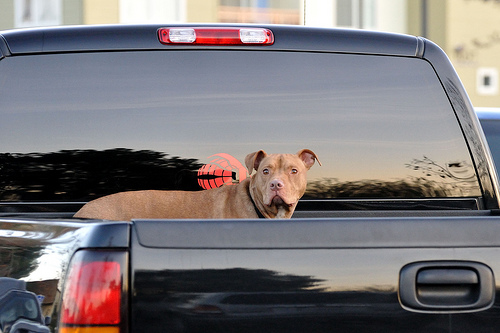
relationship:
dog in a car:
[72, 150, 321, 220] [1, 25, 500, 332]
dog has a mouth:
[72, 150, 321, 220] [266, 194, 296, 208]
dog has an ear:
[72, 150, 321, 220] [245, 150, 264, 174]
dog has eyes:
[72, 150, 321, 220] [262, 166, 300, 177]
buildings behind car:
[1, 1, 499, 113] [1, 25, 500, 332]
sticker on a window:
[198, 151, 246, 192] [1, 50, 480, 204]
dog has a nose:
[72, 150, 321, 220] [270, 180, 282, 190]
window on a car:
[1, 50, 480, 204] [1, 25, 500, 332]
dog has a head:
[72, 150, 321, 220] [241, 147, 321, 208]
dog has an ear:
[72, 150, 321, 220] [298, 149, 321, 169]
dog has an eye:
[72, 150, 321, 220] [262, 166, 270, 174]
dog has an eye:
[72, 150, 321, 220] [291, 168, 298, 174]